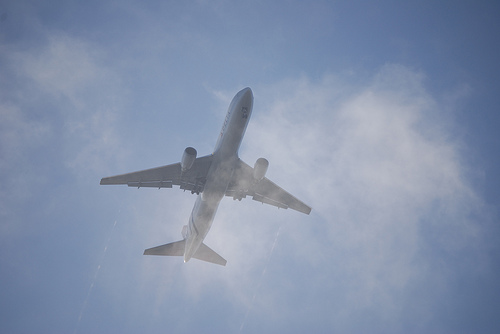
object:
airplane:
[100, 85, 314, 266]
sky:
[204, 48, 234, 70]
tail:
[141, 240, 228, 268]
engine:
[178, 146, 201, 173]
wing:
[99, 147, 210, 193]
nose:
[229, 86, 255, 112]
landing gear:
[191, 177, 200, 194]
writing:
[219, 111, 232, 136]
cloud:
[363, 91, 389, 124]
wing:
[240, 157, 314, 218]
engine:
[250, 158, 271, 182]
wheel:
[242, 112, 248, 118]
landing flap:
[128, 181, 174, 189]